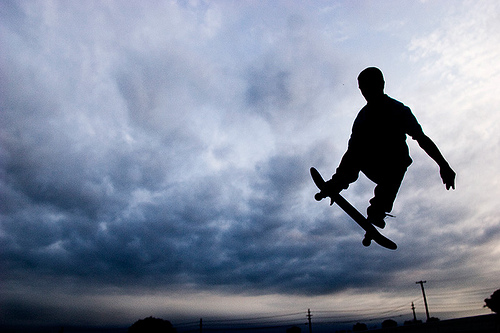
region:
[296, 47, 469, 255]
silhouette of a skateboarder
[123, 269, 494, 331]
power lines in twilight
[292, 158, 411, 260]
silhouette of a skateboard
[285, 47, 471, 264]
person doing skateboard trick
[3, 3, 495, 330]
person jumping a skateboard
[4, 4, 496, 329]
person playing on cloudy day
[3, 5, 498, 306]
sky of dark grey clouds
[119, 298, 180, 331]
silhouette of a tree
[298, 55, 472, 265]
person holding onto skateboard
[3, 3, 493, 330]
person out at dusk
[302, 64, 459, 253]
The silhouette of a man doing skateboard tricks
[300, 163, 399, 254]
A skateboard in the air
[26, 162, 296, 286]
The dark cloudy sky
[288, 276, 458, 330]
Telephone poles by the street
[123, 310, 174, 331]
The tip of a man's head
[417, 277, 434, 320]
A tall telephone pole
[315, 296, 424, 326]
Telephone wires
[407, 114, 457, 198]
A man's arm extended in the air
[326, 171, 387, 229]
A pair of shoes on the skateboard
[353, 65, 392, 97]
A man's head in shadow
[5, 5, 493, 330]
a skateboarder flying at dusk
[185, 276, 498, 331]
power lines are on the horizon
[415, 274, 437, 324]
a telephone pole is near the power lines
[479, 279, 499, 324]
a tree is near the poles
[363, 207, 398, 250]
the boy's foot is off the skateboard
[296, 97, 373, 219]
the boy is holding the board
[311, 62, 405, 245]
the boy is looking down at the board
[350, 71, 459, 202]
the boy's arm is in the air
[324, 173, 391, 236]
the skater has skateboard shoes on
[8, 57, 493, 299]
dark clouds are rolling in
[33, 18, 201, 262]
Clouds in the sky.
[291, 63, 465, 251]
Person on a skateboard.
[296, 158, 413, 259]
Skateboard in the air.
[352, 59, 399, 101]
Person has short hair.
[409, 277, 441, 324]
Poles in the background.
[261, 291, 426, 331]
Powerlines on the poles.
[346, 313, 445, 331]
Trees under the powerlines.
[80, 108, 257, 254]
The clouds are bluish grey.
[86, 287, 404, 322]
The sky is white.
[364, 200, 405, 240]
Shoe is untied.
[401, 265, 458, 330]
Telephone poles in the background.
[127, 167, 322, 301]
Dark clouds in the sky.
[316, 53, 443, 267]
Young male skateboarding.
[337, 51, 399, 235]
The male has short hair.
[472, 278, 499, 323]
Tree in the background.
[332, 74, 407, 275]
The boy is wearing tennis shoes.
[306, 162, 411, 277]
There are wheels on the skateboard.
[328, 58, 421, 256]
The boy is wearing pants.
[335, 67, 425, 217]
The boy has rolled up shirt sleeves.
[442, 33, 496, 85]
White clouds in the sky.